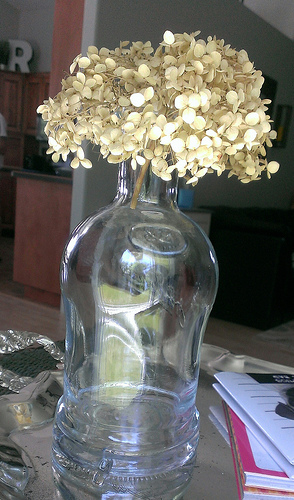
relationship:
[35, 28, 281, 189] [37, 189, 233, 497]
flower inside bottle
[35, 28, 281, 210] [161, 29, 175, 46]
flower has petal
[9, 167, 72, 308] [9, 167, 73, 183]
counter has top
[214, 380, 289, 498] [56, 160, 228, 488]
book with vase